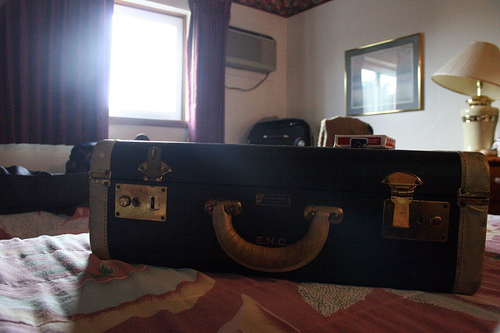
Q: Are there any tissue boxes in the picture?
A: No, there are no tissue boxes.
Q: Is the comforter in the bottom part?
A: Yes, the comforter is in the bottom of the image.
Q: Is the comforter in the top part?
A: No, the comforter is in the bottom of the image.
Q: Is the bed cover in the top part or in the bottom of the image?
A: The bed cover is in the bottom of the image.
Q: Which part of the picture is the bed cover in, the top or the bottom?
A: The bed cover is in the bottom of the image.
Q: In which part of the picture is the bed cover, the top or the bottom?
A: The bed cover is in the bottom of the image.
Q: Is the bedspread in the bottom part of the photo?
A: Yes, the bedspread is in the bottom of the image.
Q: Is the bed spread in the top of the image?
A: No, the bed spread is in the bottom of the image.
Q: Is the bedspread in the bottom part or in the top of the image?
A: The bedspread is in the bottom of the image.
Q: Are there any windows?
A: Yes, there is a window.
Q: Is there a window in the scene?
A: Yes, there is a window.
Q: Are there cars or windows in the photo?
A: Yes, there is a window.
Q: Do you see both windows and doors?
A: No, there is a window but no doors.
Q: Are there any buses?
A: No, there are no buses.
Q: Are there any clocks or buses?
A: No, there are no buses or clocks.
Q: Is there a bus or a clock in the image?
A: No, there are no buses or clocks.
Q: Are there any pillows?
A: No, there are no pillows.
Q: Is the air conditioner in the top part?
A: Yes, the air conditioner is in the top of the image.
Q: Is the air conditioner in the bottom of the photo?
A: No, the air conditioner is in the top of the image.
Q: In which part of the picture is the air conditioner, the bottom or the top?
A: The air conditioner is in the top of the image.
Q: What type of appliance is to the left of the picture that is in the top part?
A: The appliance is an air conditioner.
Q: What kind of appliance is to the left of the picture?
A: The appliance is an air conditioner.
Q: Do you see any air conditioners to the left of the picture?
A: Yes, there is an air conditioner to the left of the picture.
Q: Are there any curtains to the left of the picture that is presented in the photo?
A: No, there is an air conditioner to the left of the picture.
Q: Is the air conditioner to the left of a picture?
A: Yes, the air conditioner is to the left of a picture.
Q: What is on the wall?
A: The air conditioner is on the wall.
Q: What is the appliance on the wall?
A: The appliance is an air conditioner.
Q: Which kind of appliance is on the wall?
A: The appliance is an air conditioner.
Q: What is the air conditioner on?
A: The air conditioner is on the wall.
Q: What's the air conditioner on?
A: The air conditioner is on the wall.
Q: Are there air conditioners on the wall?
A: Yes, there is an air conditioner on the wall.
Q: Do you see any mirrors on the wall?
A: No, there is an air conditioner on the wall.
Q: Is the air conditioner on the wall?
A: Yes, the air conditioner is on the wall.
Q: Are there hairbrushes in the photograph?
A: No, there are no hairbrushes.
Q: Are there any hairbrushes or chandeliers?
A: No, there are no hairbrushes or chandeliers.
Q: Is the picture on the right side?
A: Yes, the picture is on the right of the image.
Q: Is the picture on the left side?
A: No, the picture is on the right of the image.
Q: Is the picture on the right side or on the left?
A: The picture is on the right of the image.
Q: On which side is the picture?
A: The picture is on the right of the image.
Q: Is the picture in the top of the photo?
A: Yes, the picture is in the top of the image.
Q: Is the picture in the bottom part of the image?
A: No, the picture is in the top of the image.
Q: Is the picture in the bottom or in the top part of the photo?
A: The picture is in the top of the image.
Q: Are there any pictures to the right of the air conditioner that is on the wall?
A: Yes, there is a picture to the right of the air conditioner.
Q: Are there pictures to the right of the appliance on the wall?
A: Yes, there is a picture to the right of the air conditioner.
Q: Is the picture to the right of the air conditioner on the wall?
A: Yes, the picture is to the right of the air conditioner.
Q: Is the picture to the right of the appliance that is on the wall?
A: Yes, the picture is to the right of the air conditioner.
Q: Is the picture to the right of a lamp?
A: No, the picture is to the right of the air conditioner.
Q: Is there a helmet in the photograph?
A: No, there are no helmets.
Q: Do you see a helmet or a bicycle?
A: No, there are no helmets or bicycles.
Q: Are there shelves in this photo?
A: No, there are no shelves.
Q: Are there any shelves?
A: No, there are no shelves.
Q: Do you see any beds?
A: Yes, there is a bed.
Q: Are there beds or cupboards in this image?
A: Yes, there is a bed.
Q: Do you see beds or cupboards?
A: Yes, there is a bed.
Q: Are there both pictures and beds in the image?
A: Yes, there are both a bed and a picture.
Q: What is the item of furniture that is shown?
A: The piece of furniture is a bed.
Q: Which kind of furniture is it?
A: The piece of furniture is a bed.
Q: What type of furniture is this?
A: That is a bed.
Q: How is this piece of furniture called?
A: That is a bed.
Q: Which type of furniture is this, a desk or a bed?
A: That is a bed.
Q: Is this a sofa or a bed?
A: This is a bed.